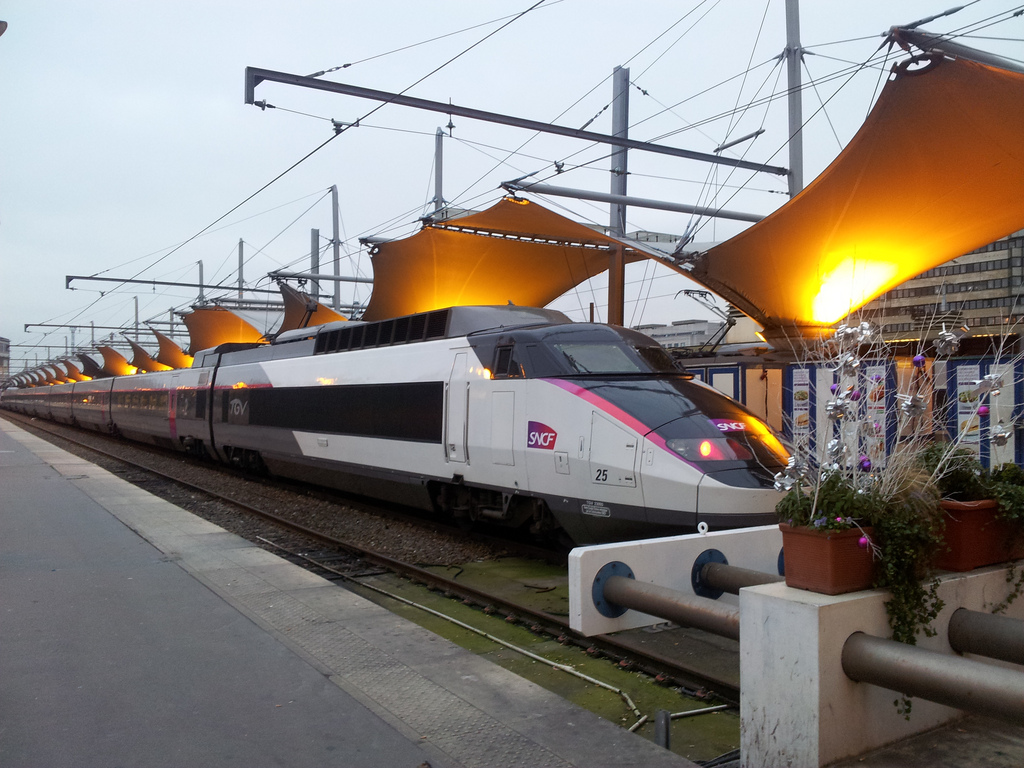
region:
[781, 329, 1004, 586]
A pot of large flowers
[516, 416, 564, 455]
A sign with the letter SYCF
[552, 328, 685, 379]
The train dark window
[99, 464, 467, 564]
Small rock on the track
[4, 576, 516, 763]
The street and the sidewalk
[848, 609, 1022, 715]
Two large metal pipes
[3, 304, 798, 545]
A train on the tracks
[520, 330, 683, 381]
Windows on a train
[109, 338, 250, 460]
Passenger car on a train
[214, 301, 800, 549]
An engine on a train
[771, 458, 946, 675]
Plants near a train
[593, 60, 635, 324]
A pole behind a train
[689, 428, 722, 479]
A light on a train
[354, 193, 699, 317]
A canopy behind a train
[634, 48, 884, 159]
Wires on some poles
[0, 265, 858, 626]
this is a train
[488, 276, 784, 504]
black trim on train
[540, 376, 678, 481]
pink trim on train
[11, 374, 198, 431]
a row of windows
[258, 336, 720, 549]
white side of train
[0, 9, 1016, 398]
canopies next to the train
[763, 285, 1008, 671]
potted plants in a box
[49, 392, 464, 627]
gravel on the tracks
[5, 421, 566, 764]
the platform is gray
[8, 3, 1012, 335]
lines above the train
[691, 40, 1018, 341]
canopy over the train platform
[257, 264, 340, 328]
canopy over the train platform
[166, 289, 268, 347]
canopy over the train platform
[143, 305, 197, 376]
canopy over the train platform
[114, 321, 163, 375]
canopy over the train platform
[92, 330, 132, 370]
canopy over the train platform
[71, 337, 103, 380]
canopy over the train platform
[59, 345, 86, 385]
canopy over the train platform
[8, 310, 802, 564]
train on a track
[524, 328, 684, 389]
windshield on a train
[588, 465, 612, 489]
number 25 on the train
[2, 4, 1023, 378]
light blue colored sky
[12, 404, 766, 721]
tracks under a train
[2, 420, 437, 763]
paved grey roadway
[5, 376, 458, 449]
black stripe on a train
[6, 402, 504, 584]
rocks on the side of a train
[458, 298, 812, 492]
front black part of a train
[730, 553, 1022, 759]
cement block holding planters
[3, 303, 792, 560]
A long mostly grey and white train.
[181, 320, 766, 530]
white gray and black passenger train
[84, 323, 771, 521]
passenger train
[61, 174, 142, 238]
white clouds in blue sky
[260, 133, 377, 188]
white clouds in blue sky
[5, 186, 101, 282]
white clouds in blue sky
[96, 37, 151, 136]
white clouds in blue sky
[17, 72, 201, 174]
white clouds in blue sky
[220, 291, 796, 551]
A train car on a track.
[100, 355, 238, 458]
A train car on a track.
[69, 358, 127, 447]
A train car on a track.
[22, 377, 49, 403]
A train car on a track.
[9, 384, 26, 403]
A train car on a track.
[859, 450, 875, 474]
A flower on a stem.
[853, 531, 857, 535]
A flower on a stem.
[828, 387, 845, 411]
A flower on a stem.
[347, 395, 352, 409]
a window on the train